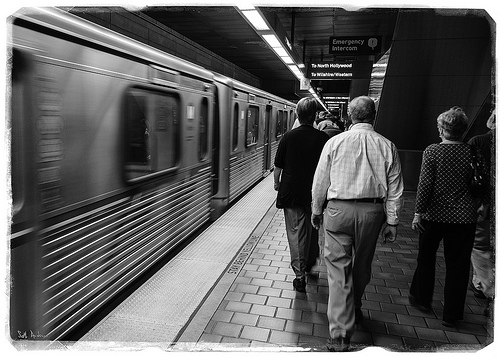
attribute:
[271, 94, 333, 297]
person — walking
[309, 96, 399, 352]
man — walking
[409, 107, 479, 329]
woman — walking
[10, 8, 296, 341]
train — stopped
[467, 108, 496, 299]
woman — walking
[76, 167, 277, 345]
zone — safety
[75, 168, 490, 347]
floor — platform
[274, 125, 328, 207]
shirt — black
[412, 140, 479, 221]
shirt — blouse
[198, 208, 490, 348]
floor — tiled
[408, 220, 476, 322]
pants — black